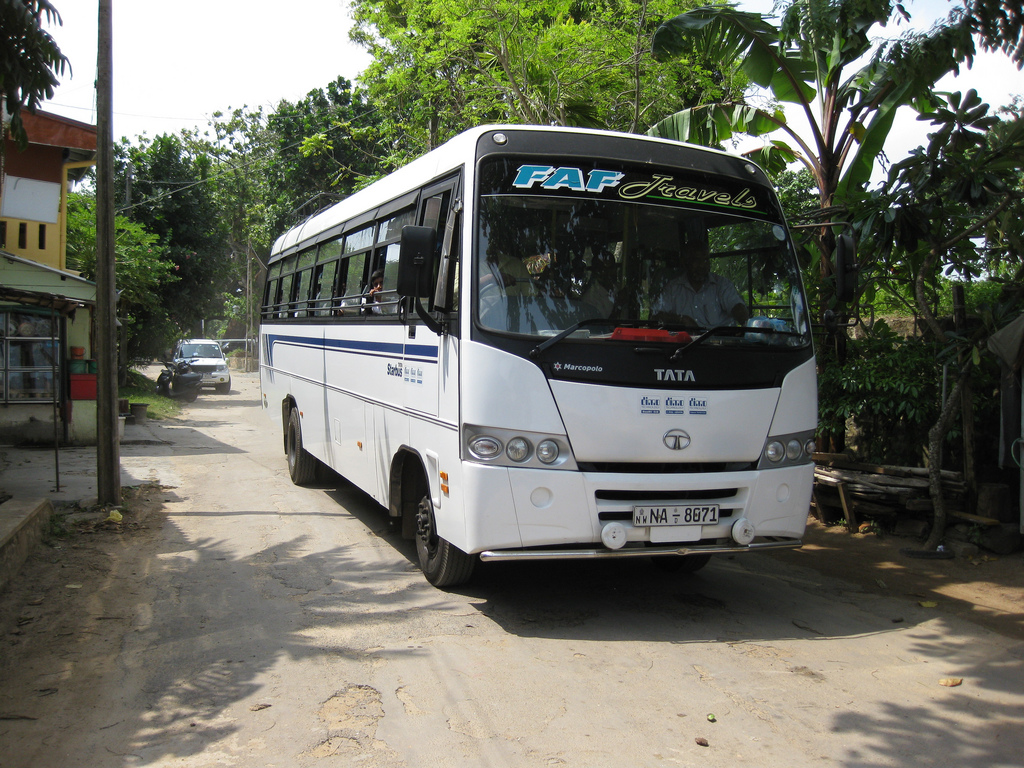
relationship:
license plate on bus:
[633, 493, 731, 537] [258, 122, 823, 583]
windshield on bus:
[463, 158, 803, 351] [258, 122, 823, 583]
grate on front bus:
[601, 493, 749, 548] [258, 122, 823, 583]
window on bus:
[364, 251, 386, 306] [258, 122, 823, 583]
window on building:
[12, 206, 23, 250] [4, 61, 100, 485]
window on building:
[30, 217, 59, 257] [14, 121, 159, 517]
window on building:
[19, 323, 69, 362] [2, 111, 130, 451]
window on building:
[6, 329, 56, 362] [6, 150, 112, 470]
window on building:
[12, 355, 58, 405] [2, 109, 143, 499]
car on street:
[159, 333, 229, 401] [166, 372, 603, 761]